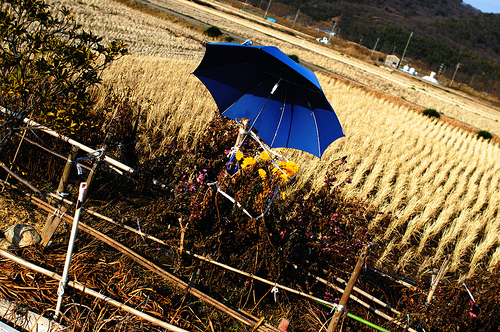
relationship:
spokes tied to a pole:
[189, 40, 349, 159] [211, 116, 251, 207]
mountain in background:
[356, 0, 498, 101] [128, 3, 498, 99]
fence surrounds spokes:
[3, 107, 448, 331] [189, 40, 349, 159]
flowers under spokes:
[157, 124, 303, 235] [189, 40, 349, 159]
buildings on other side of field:
[312, 26, 439, 86] [142, 3, 495, 246]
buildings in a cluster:
[312, 26, 439, 86] [382, 49, 442, 83]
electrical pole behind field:
[393, 29, 420, 74] [142, 3, 495, 246]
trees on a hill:
[350, 12, 489, 58] [356, 0, 498, 101]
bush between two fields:
[198, 19, 228, 45] [142, 3, 495, 246]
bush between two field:
[198, 19, 228, 45] [0, 0, 500, 295]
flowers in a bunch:
[157, 124, 303, 235] [188, 153, 273, 218]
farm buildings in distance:
[382, 49, 442, 83] [128, 3, 498, 99]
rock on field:
[4, 217, 44, 255] [0, 0, 500, 295]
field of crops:
[142, 3, 495, 246] [368, 129, 462, 189]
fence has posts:
[3, 107, 448, 331] [40, 137, 88, 330]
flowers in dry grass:
[157, 124, 303, 235] [8, 165, 300, 314]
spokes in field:
[189, 40, 349, 159] [142, 3, 495, 246]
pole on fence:
[311, 295, 386, 331] [3, 107, 448, 331]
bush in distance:
[198, 19, 228, 45] [128, 3, 498, 99]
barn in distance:
[381, 51, 399, 73] [128, 3, 498, 99]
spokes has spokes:
[189, 40, 349, 159] [221, 76, 327, 149]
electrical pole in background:
[394, 30, 416, 79] [128, 3, 498, 99]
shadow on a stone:
[10, 221, 28, 248] [4, 217, 44, 255]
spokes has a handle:
[189, 40, 349, 159] [225, 151, 243, 175]